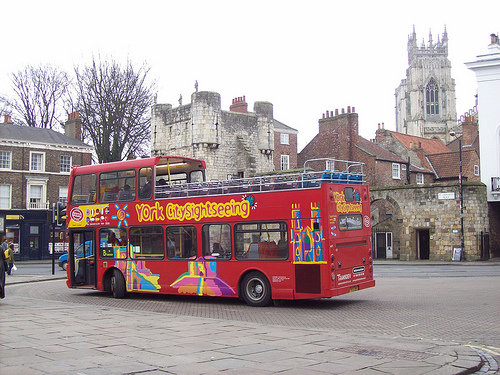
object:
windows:
[138, 166, 153, 200]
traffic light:
[58, 205, 66, 212]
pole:
[52, 202, 55, 275]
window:
[392, 162, 401, 179]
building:
[152, 26, 500, 266]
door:
[375, 231, 393, 260]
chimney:
[230, 95, 248, 113]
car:
[58, 239, 133, 271]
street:
[307, 303, 405, 329]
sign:
[135, 199, 250, 223]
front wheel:
[109, 268, 126, 298]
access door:
[69, 227, 98, 291]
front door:
[21, 222, 45, 261]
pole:
[459, 140, 466, 262]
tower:
[406, 24, 449, 67]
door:
[415, 229, 429, 260]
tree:
[65, 57, 158, 165]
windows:
[129, 226, 165, 260]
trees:
[0, 66, 67, 130]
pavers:
[365, 292, 499, 339]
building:
[0, 111, 94, 261]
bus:
[64, 155, 376, 308]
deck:
[154, 158, 367, 200]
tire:
[241, 271, 272, 306]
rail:
[153, 158, 366, 200]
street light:
[449, 132, 457, 137]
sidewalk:
[0, 329, 300, 369]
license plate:
[349, 285, 358, 292]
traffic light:
[59, 215, 66, 222]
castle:
[290, 202, 327, 265]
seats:
[319, 170, 331, 187]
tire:
[62, 261, 69, 271]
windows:
[69, 173, 97, 205]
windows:
[98, 226, 127, 259]